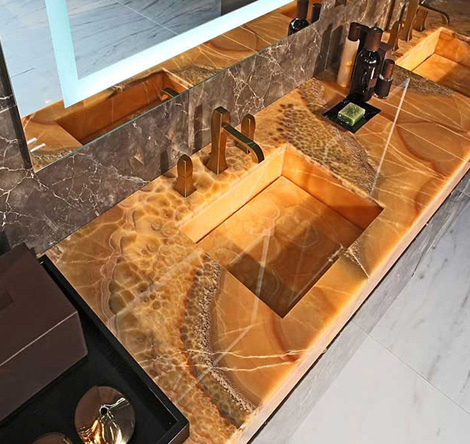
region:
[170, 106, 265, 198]
A faucet on a sink.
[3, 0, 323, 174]
A mirror on a wall.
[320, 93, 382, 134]
Soap in a soap dish.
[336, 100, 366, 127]
A bar of green soap.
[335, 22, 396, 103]
Bottles on a counter.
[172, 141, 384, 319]
A square bathroom sink.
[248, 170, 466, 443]
A white tile floor.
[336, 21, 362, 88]
One bottle on a counter.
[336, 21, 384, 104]
Two bottles on a sink.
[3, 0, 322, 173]
Part of a mirror.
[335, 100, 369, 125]
The green bar of soap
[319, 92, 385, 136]
The black dish the green soap is on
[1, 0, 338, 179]
The mirror above the sink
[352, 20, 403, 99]
The two dark bottles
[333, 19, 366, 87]
White bottle with a brown cap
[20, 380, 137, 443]
The shiny, circular gold items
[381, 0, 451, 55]
The faucet on the right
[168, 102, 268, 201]
The faucet on the left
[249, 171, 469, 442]
The large white tiles on the ground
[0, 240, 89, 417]
The large brown box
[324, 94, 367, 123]
The black dish the soap is on.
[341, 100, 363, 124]
The green bar of soap.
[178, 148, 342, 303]
The square shape of the sink.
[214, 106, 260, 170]
The faucet of the sink.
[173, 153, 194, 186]
The left knob on the sink's counter.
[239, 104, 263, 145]
The right knob on the sink's counter.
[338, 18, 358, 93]
The beige bottle on the counter.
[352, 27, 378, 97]
The larger brown bottle on the counter.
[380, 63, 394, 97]
The small bottle on the counter.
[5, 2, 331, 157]
The mirror above the sink.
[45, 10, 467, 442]
A bathroom counter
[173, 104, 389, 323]
This is a sink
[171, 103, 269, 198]
A water faucet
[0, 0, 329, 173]
A mirror is on the wall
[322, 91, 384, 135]
A soap dish is on the counter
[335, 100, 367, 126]
Soap is in the dish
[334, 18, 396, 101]
Toiletries are on the counter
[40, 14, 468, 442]
The counter is made of marble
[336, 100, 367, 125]
The soap is green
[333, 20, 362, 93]
A bottle of shampoo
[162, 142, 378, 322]
Square sink in the bathroom.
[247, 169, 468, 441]
Grey marble on the floor.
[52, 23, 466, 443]
Orange shaded marble on the counter.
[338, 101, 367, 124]
Green bar of soap.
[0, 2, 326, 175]
Mirror on the wall.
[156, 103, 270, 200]
Brass colored faucet on sink.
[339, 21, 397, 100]
Bottles on the counter.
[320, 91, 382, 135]
Black soap dish on counter.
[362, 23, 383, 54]
Brown top on bottle.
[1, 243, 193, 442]
Black tray on the counter.